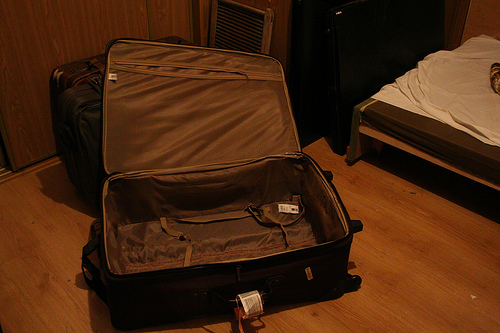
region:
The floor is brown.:
[407, 220, 487, 320]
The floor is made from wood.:
[390, 242, 485, 327]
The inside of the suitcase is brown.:
[108, 176, 327, 247]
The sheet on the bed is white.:
[433, 70, 483, 107]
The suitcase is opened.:
[67, 28, 369, 329]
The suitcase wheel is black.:
[348, 266, 363, 293]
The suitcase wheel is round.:
[349, 269, 365, 290]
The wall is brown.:
[13, 18, 50, 53]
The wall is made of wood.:
[18, 8, 48, 68]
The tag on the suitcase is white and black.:
[233, 288, 270, 319]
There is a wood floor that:
[426, 239, 445, 298]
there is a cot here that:
[438, 80, 463, 139]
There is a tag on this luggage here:
[241, 295, 270, 332]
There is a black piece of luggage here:
[331, 24, 373, 109]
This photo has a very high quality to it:
[121, 40, 348, 305]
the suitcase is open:
[45, 13, 382, 320]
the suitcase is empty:
[74, 48, 385, 328]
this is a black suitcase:
[74, 33, 371, 311]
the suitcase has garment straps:
[73, 20, 385, 330]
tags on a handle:
[216, 290, 298, 325]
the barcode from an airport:
[206, 279, 290, 321]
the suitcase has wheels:
[70, 45, 396, 331]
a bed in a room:
[349, 51, 483, 196]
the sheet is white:
[340, 34, 495, 171]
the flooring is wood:
[387, 191, 474, 266]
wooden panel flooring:
[4, 134, 498, 309]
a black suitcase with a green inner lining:
[78, 35, 365, 314]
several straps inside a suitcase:
[105, 202, 331, 272]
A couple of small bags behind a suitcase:
[18, 36, 239, 199]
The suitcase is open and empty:
[85, 27, 370, 323]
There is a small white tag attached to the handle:
[199, 290, 298, 328]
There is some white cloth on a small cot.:
[331, 28, 498, 217]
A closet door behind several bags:
[2, 9, 184, 182]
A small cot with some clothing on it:
[325, 26, 498, 227]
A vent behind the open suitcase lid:
[193, 8, 278, 98]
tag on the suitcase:
[236, 289, 262, 318]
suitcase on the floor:
[78, 42, 362, 306]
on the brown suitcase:
[237, 290, 263, 322]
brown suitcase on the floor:
[93, 34, 364, 325]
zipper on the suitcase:
[110, 57, 280, 84]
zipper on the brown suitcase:
[111, 52, 281, 90]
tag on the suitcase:
[108, 70, 119, 82]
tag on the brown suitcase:
[107, 72, 117, 82]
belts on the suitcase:
[150, 205, 292, 262]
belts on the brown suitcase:
[152, 200, 302, 257]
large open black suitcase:
[79, 35, 364, 327]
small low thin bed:
[348, 29, 499, 224]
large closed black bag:
[49, 34, 194, 207]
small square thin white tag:
[235, 288, 266, 321]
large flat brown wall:
[0, 1, 288, 173]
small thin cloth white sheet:
[369, 34, 499, 146]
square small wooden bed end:
[349, 91, 383, 163]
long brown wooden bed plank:
[361, 123, 499, 194]